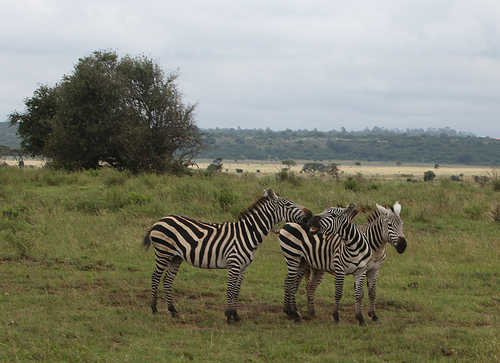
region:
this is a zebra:
[273, 168, 369, 332]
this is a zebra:
[333, 170, 429, 337]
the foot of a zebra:
[139, 252, 164, 314]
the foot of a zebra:
[157, 250, 183, 320]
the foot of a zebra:
[214, 260, 245, 358]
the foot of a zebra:
[278, 250, 300, 337]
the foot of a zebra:
[278, 257, 305, 324]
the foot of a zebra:
[299, 274, 319, 321]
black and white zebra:
[141, 187, 310, 325]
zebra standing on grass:
[278, 202, 374, 327]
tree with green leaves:
[11, 52, 208, 177]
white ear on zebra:
[374, 201, 389, 219]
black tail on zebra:
[141, 224, 152, 255]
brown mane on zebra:
[235, 192, 270, 224]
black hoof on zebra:
[225, 308, 235, 327]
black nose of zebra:
[397, 237, 408, 254]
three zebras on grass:
[142, 189, 412, 326]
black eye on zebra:
[283, 201, 290, 207]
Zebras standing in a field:
[135, 179, 427, 326]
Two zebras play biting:
[225, 180, 372, 273]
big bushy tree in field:
[12, 43, 211, 175]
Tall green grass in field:
[21, 178, 139, 234]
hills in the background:
[210, 118, 489, 158]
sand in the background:
[227, 160, 456, 174]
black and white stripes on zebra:
[172, 226, 236, 253]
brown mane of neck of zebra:
[235, 192, 262, 219]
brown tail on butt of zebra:
[139, 215, 159, 250]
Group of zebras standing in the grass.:
[125, 180, 420, 330]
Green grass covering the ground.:
[28, 300, 140, 358]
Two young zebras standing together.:
[282, 194, 417, 334]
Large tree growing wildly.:
[7, 46, 216, 178]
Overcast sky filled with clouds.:
[192, 4, 498, 139]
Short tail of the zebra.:
[132, 221, 157, 255]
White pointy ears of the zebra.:
[369, 195, 428, 216]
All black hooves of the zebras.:
[132, 296, 384, 328]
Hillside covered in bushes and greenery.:
[200, 113, 499, 174]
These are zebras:
[130, 177, 422, 341]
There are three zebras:
[111, 166, 421, 340]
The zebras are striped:
[137, 172, 417, 336]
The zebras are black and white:
[147, 171, 408, 341]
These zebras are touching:
[270, 187, 339, 248]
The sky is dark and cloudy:
[2, 2, 499, 172]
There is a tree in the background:
[17, 37, 214, 189]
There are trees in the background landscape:
[3, 105, 497, 180]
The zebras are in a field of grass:
[0, 160, 495, 356]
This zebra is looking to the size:
[369, 187, 419, 260]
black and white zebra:
[136, 168, 311, 322]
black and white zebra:
[289, 173, 411, 311]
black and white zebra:
[360, 188, 410, 252]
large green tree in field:
[9, 54, 209, 171]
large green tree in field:
[4, 38, 222, 183]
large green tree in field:
[13, 40, 205, 179]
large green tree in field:
[1, 40, 213, 191]